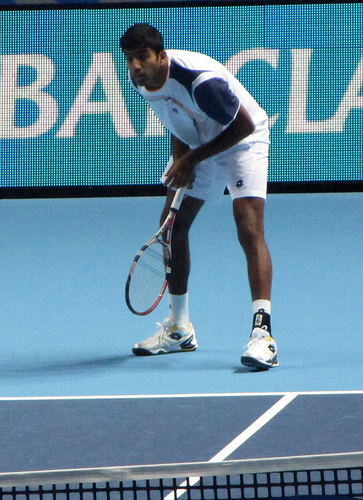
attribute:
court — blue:
[34, 229, 94, 330]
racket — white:
[111, 192, 194, 337]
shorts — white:
[228, 155, 275, 197]